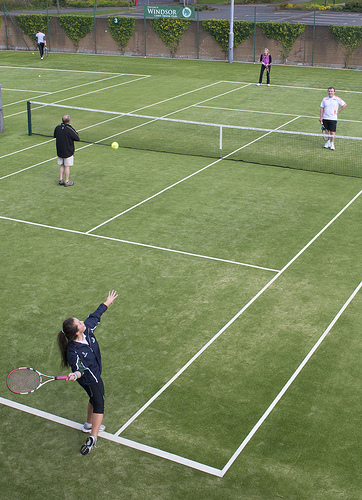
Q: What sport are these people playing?
A: Tennis.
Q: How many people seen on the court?
A: Five.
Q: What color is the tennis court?
A: Green and white.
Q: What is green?
A: The turf.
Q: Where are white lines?
A: On the court.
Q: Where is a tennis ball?
A: In the air.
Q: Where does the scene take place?
A: At a tennis court.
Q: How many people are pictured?
A: Five.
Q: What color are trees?
A: Green.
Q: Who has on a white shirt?
A: Man on right.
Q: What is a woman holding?
A: Tennis racket.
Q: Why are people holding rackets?
A: To play tennis.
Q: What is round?
A: Tennis ball.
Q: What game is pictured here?
A: Tennis.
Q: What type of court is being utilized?
A: Grass.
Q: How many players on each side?
A: Two.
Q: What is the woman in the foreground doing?
A: Preparing to hit the ball.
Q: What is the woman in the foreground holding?
A: Tennis racquet.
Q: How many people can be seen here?
A: Five.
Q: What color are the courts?
A: Green.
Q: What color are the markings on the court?
A: White.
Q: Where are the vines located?
A: The fence.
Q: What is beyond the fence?
A: Parking lot.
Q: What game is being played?
A: Tennis.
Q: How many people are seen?
A: 5.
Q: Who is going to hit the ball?
A: Lady in front.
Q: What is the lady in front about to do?
A: Hit ball.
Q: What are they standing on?
A: Tennis court.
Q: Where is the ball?
A: In the air.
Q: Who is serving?
A: Woman in front.